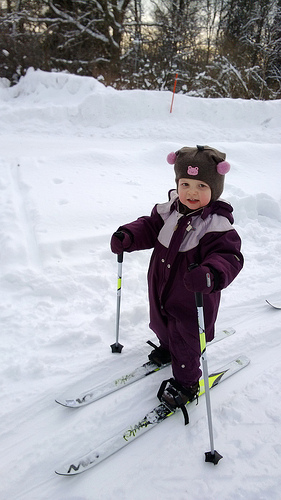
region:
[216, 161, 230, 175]
the pompom on the child's hat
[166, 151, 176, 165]
the pompom on the child's hat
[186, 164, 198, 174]
the design on the hat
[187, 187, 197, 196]
the nose on the small child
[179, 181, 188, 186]
the eye on the small child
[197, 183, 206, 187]
the eye on the small child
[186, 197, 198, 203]
the mouth on the small child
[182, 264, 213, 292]
the glove on the hand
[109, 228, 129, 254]
the glove on the hand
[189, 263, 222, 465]
the ski pole in the child's hand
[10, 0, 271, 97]
The trees behind the girl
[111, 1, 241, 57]
The light coming through the trees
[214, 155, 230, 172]
The pink ball on the little girls hat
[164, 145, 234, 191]
The little girls brown snow hat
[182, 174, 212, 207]
The little girls face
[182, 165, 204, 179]
The pink bear on the little girls hat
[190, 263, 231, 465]
The little girls ski poles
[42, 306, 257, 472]
Small child size ski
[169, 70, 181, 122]
A red pole in the ground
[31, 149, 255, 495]
A little girl who is skiing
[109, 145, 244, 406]
A small child in purple and a hat.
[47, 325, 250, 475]
White, black and yellow skis on a kid.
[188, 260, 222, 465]
A silver, yellow and black left hand ski pole.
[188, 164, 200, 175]
A small pink teddy bear head on a kid's hat.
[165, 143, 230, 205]
A small brown and pink hat on a child.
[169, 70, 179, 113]
A red pole back in the snow.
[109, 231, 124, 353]
A silver, yellow and black pole in a kid's right hand.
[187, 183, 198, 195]
A nose on a kid's face.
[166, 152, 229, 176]
Two pink balls on a kid's hat.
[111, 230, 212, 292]
Purple gloves on a child.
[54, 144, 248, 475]
a small child on skis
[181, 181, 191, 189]
a small child's right eye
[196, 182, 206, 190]
a small child's left eye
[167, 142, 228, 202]
a small child's winter cap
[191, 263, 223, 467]
a small child's left ski pole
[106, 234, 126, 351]
a small child's right ski pole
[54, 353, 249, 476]
a small child's left ski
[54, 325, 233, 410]
a small child's right ski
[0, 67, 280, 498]
a snowy yard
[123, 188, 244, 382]
a small child's snow suit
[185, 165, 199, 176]
pink bear on brown hat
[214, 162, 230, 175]
pink pom pom on the brown hat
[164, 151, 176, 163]
pink pom pom on brown hat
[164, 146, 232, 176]
brown hat on little girl's head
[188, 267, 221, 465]
ski pole in girl's hand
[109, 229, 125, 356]
ski pole in girl's hand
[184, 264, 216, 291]
glove on little girl's hand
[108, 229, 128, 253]
glove on little girl's hand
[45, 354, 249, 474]
skis on girls feet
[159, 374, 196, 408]
boot on girl's foot